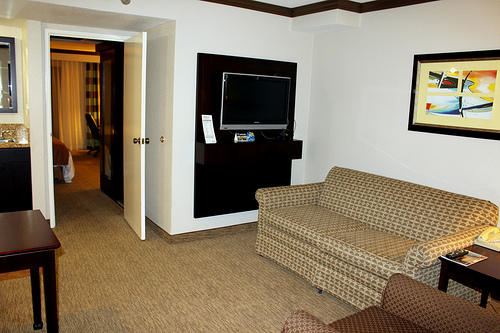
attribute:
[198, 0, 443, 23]
ceiling — WHITE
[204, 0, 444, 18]
trim — browm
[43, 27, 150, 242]
door — large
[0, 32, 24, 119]
mirror — LARGE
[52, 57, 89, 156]
curtains — nice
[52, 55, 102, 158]
window — clear